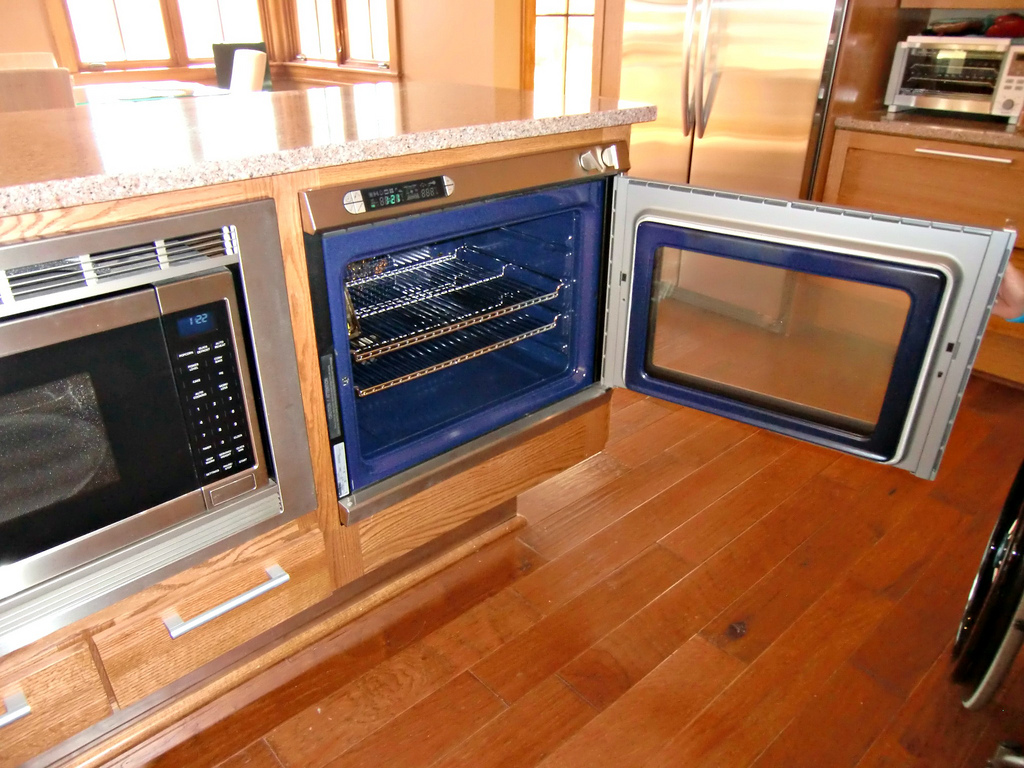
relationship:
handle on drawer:
[142, 568, 331, 642] [67, 513, 366, 702]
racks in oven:
[343, 227, 560, 400] [293, 172, 1015, 538]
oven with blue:
[289, 148, 1013, 522] [309, 179, 668, 534]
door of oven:
[622, 161, 1020, 516] [306, 157, 650, 514]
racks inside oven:
[349, 241, 578, 416] [306, 157, 650, 514]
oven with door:
[301, 173, 1018, 527] [609, 164, 1014, 493]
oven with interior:
[301, 173, 1018, 527] [313, 174, 640, 509]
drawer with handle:
[62, 527, 406, 702] [155, 548, 294, 654]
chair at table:
[179, 23, 300, 116] [10, 60, 244, 115]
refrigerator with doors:
[611, 0, 847, 198] [607, 2, 854, 229]